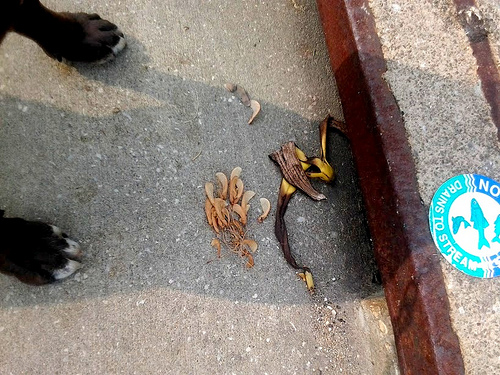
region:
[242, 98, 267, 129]
Small brown seedling on the pavement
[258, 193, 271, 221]
Small brown seedling on the pavement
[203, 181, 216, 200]
Small brown seedling on the pavement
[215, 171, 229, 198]
Small brown seedling on the pavement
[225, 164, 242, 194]
Small brown seedling on the pavement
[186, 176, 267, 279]
Small brown seedling on the pavement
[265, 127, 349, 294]
Banana peel on the paveemnt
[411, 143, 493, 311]
Blue and white button on the pavement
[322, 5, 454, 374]
Small brown edge of the pavement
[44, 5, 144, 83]
Black and whtie paw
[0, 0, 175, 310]
A dog's paws on the ground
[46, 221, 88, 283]
White tips of the black paws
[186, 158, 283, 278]
Discarded flower petals on the ground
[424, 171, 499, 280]
A blue and white logo on the ground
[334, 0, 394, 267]
A red painted section of the curb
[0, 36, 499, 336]
The black shadow of the dog on the ground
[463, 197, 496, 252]
A blue shark on the small logo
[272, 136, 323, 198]
A rotten brown peel on the banana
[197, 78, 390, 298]
Litter thrown by the curb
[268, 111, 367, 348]
a banana peel on the ground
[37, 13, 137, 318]
black and white paws of dog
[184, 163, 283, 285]
seedlings on the ground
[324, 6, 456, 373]
red paint on the curb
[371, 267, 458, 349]
shadow from a chain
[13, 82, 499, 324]
shadow from the dog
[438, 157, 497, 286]
a blue and white sticker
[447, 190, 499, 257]
three fish on the sticker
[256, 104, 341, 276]
a brown and yellow banana peel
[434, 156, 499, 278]
white letters on sticker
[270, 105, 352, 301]
rotting banana peel.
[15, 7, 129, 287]
Black and white paws.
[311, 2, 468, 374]
Rusty curb.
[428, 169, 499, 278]
Circular sticker about drains to stream.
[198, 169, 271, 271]
Seeds from a tree.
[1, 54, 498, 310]
Shadow of an animal.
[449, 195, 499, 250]
Three blue fish.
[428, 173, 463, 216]
The word drains.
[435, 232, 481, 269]
The word stream on the sticker.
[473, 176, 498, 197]
The word no on the sticker.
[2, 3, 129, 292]
black paws of a dog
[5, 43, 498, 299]
shadow of a dog on the ground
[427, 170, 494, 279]
a blue and green sticker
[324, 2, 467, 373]
a red painted curb to sidewalk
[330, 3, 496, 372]
the sidewalk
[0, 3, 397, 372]
the concrete street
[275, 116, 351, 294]
a old banana peel in the street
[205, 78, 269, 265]
a stack of winged tree seeds in street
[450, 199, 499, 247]
green fish on a sticker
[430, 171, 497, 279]
sticker on the sidewalk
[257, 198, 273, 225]
tree seed on the grey ground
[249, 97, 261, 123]
tree seed on the grey ground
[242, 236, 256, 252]
tree seed on the grey ground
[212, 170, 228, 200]
tree seed on the grey ground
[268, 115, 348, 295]
the banana peel is brown and yellow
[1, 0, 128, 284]
the two feet of an animal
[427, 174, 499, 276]
the sticker is aqua, blue and white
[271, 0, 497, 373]
the banana peel near the curb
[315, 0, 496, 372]
the sticker near the curb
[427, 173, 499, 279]
the pictures of the sea life on the sticker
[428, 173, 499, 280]
the letters on the sticker